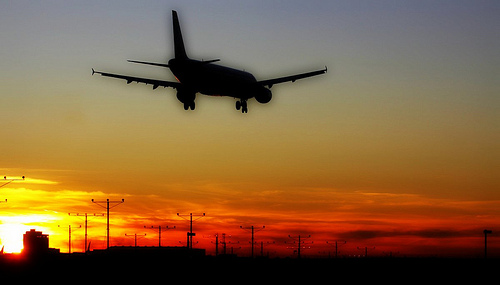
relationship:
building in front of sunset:
[22, 228, 50, 258] [7, 173, 20, 253]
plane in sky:
[89, 9, 328, 114] [127, 115, 497, 206]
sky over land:
[13, 18, 495, 209] [20, 245, 490, 282]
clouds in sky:
[12, 173, 488, 251] [29, 112, 493, 212]